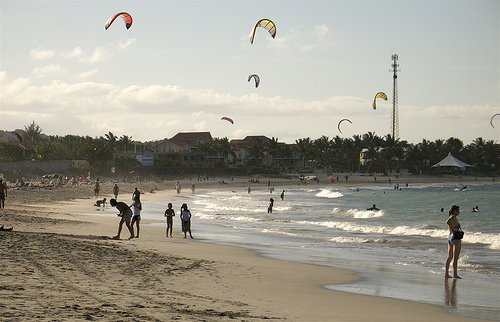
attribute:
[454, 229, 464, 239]
bag — black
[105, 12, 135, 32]
kite — orange, black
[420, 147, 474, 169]
top — white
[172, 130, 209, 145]
roof — red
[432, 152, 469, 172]
roof — white 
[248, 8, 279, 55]
kite — black, orange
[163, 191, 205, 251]
people — standing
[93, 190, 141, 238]
man — bending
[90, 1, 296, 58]
kite — orange 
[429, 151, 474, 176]
white canopy — large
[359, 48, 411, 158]
tower — distant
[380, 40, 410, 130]
tower — tall, metal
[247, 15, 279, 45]
kite — flying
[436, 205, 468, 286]
girl — standing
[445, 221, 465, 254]
bikini — blue